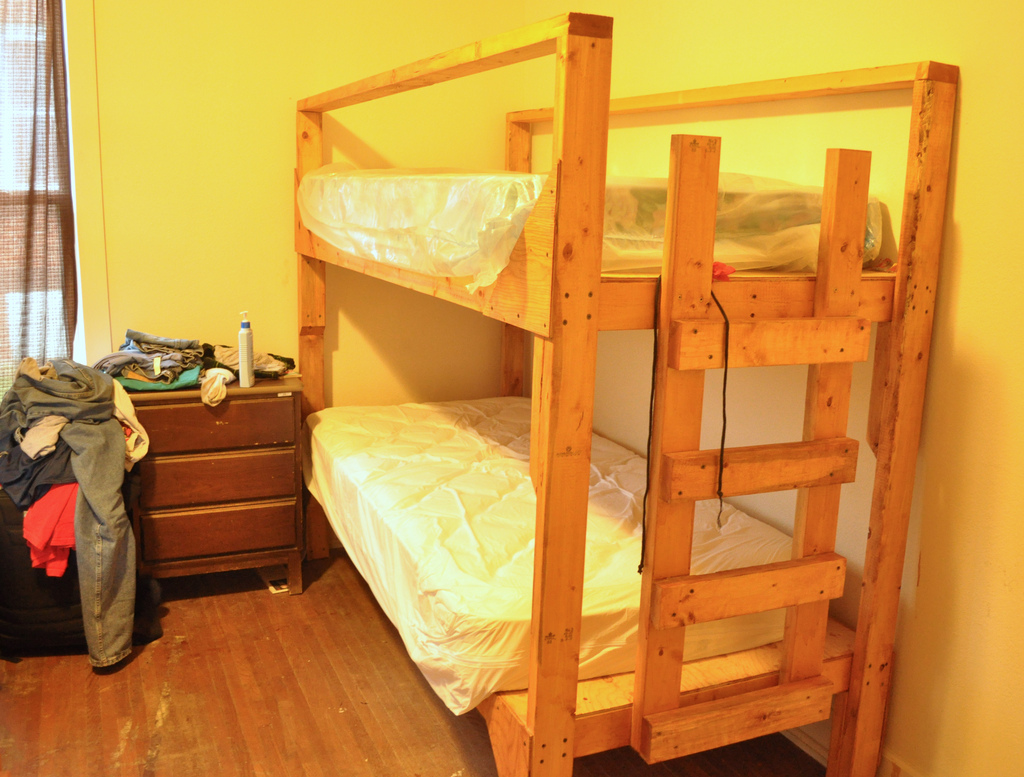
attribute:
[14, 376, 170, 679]
clothing — dirty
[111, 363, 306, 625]
dresser — brown, wooden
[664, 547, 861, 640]
slat — wooden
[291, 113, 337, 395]
slat — wooden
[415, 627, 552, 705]
mattress protector — white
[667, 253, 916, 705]
ladder — wooden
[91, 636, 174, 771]
floor — scuffed, wooden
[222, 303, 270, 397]
bottle — white, blue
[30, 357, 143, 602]
clothing — unfolded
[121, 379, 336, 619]
dresser — small, wooden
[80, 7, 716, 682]
wall — yellow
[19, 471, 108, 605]
shirt — red